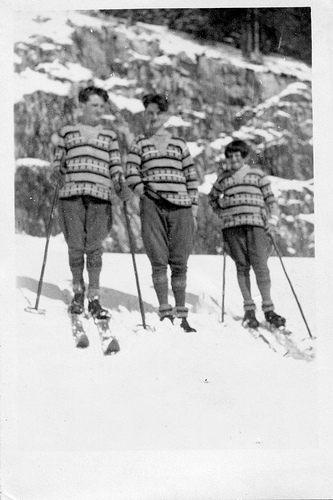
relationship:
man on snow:
[124, 84, 202, 339] [55, 318, 326, 491]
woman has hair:
[204, 123, 314, 347] [213, 129, 253, 159]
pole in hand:
[29, 171, 77, 366] [39, 152, 80, 177]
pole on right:
[29, 171, 77, 366] [33, 216, 80, 427]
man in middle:
[124, 84, 207, 258] [127, 55, 214, 420]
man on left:
[124, 84, 207, 258] [41, 112, 139, 468]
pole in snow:
[29, 171, 77, 366] [55, 318, 326, 491]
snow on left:
[55, 318, 326, 491] [41, 112, 139, 468]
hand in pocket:
[39, 152, 80, 177] [54, 162, 111, 190]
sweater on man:
[115, 130, 214, 189] [124, 84, 202, 339]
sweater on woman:
[115, 130, 214, 189] [206, 135, 289, 334]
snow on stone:
[55, 318, 326, 491] [177, 69, 209, 124]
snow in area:
[55, 318, 326, 491] [73, 35, 326, 357]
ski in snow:
[220, 311, 274, 352] [55, 318, 326, 491]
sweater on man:
[115, 130, 214, 189] [124, 84, 207, 258]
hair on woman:
[213, 129, 253, 159] [206, 135, 289, 334]